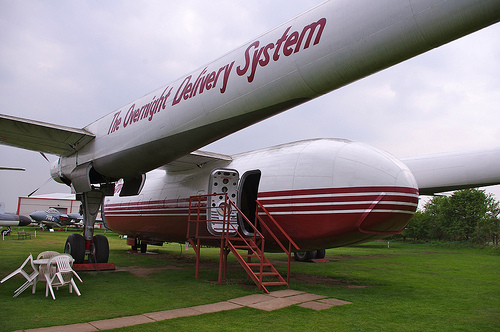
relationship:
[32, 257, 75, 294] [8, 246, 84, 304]
table with chairs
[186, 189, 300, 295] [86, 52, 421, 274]
ladder to enter plane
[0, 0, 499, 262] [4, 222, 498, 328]
airplane on grass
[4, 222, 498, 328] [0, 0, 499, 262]
grass around airplane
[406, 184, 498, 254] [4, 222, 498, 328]
trees at edge of grass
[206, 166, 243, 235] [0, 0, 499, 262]
airplane door leading inside airplane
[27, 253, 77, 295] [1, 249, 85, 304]
table has chairs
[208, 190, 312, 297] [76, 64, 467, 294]
ladder for boarding plane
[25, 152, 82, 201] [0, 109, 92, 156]
propeller on wing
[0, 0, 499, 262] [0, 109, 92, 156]
airplane has wing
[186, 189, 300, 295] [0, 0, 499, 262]
ladder going up into airplane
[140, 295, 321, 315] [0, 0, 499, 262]
walkway to airplane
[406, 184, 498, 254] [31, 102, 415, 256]
trees behind plane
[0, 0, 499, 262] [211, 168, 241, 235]
airplane has door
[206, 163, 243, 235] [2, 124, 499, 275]
airplane door on airplane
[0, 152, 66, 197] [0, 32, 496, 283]
propeller on plane